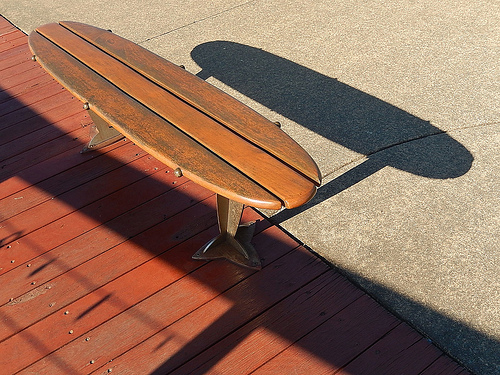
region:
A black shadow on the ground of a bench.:
[190, 39, 474, 181]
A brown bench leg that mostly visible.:
[192, 184, 262, 270]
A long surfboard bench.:
[29, 20, 321, 271]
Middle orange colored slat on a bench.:
[36, 21, 318, 209]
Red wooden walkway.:
[0, 15, 464, 373]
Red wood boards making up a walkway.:
[0, 14, 469, 373]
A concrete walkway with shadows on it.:
[2, 2, 498, 364]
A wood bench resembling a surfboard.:
[27, 18, 323, 273]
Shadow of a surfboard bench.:
[190, 41, 474, 184]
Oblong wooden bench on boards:
[30, 17, 317, 208]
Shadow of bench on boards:
[187, 35, 472, 175]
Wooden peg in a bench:
[171, 168, 183, 179]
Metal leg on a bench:
[189, 184, 264, 275]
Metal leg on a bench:
[77, 108, 117, 146]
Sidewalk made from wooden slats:
[1, 15, 466, 373]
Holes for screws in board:
[61, 308, 76, 336]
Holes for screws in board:
[21, 262, 42, 285]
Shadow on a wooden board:
[70, 288, 120, 320]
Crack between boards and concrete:
[299, 242, 467, 369]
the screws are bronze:
[170, 164, 186, 180]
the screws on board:
[68, 49, 299, 211]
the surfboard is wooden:
[74, 35, 322, 200]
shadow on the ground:
[202, 30, 475, 187]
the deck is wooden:
[2, 85, 302, 366]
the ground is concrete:
[305, 40, 496, 307]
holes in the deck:
[10, 230, 88, 368]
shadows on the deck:
[23, 215, 335, 370]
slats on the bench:
[35, 19, 321, 227]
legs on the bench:
[84, 111, 277, 263]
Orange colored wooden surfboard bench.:
[30, 19, 322, 271]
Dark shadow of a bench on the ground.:
[190, 37, 474, 182]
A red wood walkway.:
[0, 14, 467, 373]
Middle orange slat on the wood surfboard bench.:
[37, 24, 317, 209]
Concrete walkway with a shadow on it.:
[1, 1, 498, 366]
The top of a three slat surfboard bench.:
[27, 22, 322, 213]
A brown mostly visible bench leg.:
[192, 189, 263, 273]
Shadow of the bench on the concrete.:
[189, 40, 474, 183]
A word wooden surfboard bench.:
[28, 19, 320, 275]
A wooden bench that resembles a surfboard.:
[25, 20, 322, 272]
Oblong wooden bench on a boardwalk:
[25, 17, 318, 210]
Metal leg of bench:
[190, 189, 262, 269]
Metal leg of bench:
[82, 111, 114, 142]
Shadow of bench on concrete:
[192, 34, 486, 184]